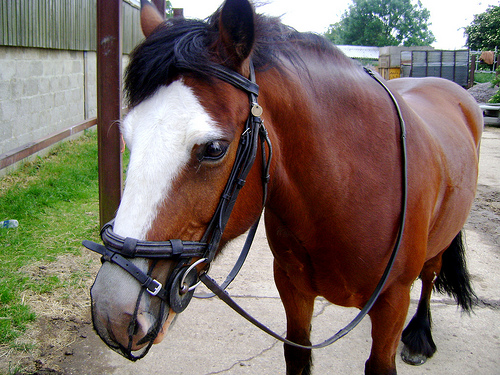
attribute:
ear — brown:
[213, 4, 258, 79]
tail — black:
[430, 226, 485, 320]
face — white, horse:
[81, 90, 254, 372]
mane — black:
[122, 17, 338, 104]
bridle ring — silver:
[176, 245, 221, 287]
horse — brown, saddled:
[68, 2, 495, 372]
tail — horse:
[410, 229, 489, 321]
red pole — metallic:
[93, 2, 120, 225]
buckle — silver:
[143, 275, 185, 305]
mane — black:
[127, 14, 232, 103]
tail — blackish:
[441, 234, 476, 312]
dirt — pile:
[463, 80, 497, 101]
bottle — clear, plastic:
[1, 212, 19, 227]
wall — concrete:
[0, 1, 154, 169]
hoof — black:
[401, 344, 430, 365]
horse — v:
[66, 4, 466, 349]